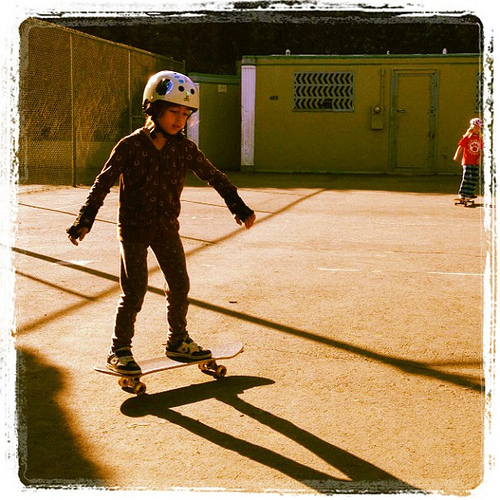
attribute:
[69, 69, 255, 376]
girl — little, young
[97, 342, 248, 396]
skateboard — brown, child sized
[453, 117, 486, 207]
child — blonde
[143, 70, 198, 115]
helmet — white, protective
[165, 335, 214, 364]
shoe — white, black, skateboarding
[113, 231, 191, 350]
sweat pants — brown, loose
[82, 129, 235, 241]
sweater — brown, stylish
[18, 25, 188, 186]
fence — metal, tall, chain link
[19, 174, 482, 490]
asphalt — concrete, clear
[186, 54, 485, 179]
building — olive green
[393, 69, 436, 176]
entrance — yellow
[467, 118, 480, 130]
helmet — pink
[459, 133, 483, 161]
shirt — red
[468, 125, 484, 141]
hair — blonde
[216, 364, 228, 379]
wheel — small